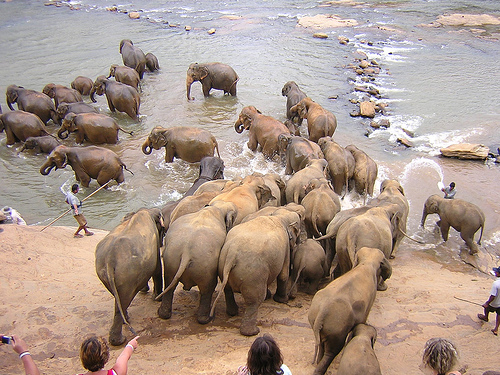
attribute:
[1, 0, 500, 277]
water — green, rushing rapidly, river, large body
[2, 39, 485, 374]
elephants — herd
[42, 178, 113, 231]
stick — long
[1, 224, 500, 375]
bank — dirt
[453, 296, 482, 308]
stick — long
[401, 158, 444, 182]
water — splashing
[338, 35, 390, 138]
rocks — in line, cluster, large, line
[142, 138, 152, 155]
trunk — curled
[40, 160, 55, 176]
trunk — curled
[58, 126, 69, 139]
trunk — curled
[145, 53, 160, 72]
elephant — baby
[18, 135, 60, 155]
elephant — baby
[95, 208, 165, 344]
elephant — dirty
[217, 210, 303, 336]
elephant — large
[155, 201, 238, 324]
elephant — large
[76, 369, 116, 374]
shirt — red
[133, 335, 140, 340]
finger — pointing